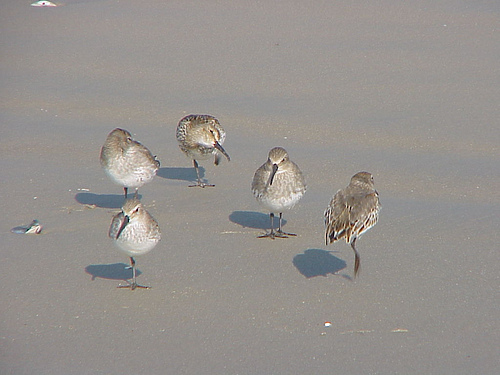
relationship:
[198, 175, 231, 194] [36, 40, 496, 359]
foot on ground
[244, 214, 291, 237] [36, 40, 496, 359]
feet on ground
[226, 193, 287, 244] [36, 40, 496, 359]
shadow on ground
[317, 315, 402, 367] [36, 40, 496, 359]
white on ground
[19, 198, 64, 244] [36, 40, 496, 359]
feather on ground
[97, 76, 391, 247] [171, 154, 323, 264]
sandpipers have shadows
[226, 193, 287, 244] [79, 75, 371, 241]
shadow of birds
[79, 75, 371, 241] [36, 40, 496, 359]
birds on ground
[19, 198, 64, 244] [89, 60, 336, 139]
feather in sand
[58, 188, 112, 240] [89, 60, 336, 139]
tracks in sand